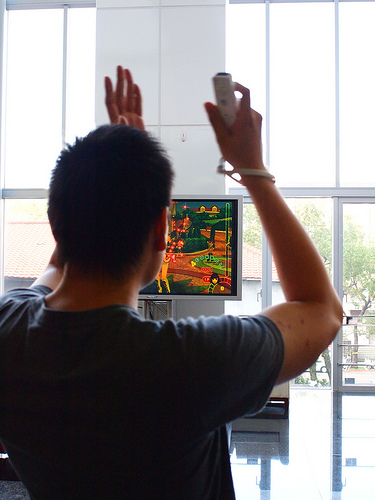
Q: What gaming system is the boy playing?
A: Wii.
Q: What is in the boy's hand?
A: Wii remote.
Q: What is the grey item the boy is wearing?
A: Shirt.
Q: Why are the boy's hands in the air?
A: Playing a game.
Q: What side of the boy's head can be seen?
A: Back.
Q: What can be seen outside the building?
A: Tree.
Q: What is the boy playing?
A: Wii.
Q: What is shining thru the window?
A: Sunlight.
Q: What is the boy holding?
A: Remote.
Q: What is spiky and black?
A: Hair.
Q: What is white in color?
A: Edge of screen.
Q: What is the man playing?
A: Wii.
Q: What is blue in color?
A: Shirt.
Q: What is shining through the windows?
A: Sun.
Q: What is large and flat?
A: Tv.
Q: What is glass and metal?
A: Doors.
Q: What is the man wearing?
A: A gray shirt.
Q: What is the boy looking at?
A: The tv.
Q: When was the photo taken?
A: Daytime.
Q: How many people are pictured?
A: One.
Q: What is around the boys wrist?
A: Strap.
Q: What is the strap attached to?
A: WII controller.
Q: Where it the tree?
A: Through the window.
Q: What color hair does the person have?
A: Black.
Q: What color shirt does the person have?
A: Gray.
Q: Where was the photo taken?
A: In a game room.